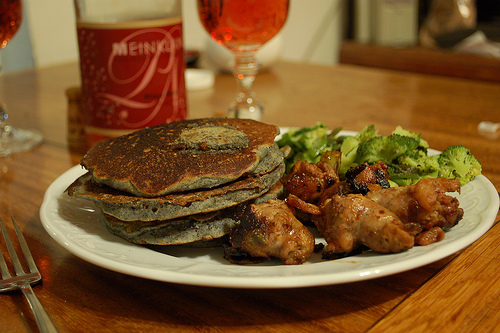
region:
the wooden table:
[8, 57, 485, 330]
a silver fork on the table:
[1, 217, 62, 331]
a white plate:
[52, 121, 487, 279]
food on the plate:
[40, 120, 499, 282]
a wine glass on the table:
[196, 8, 293, 113]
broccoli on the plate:
[294, 125, 469, 175]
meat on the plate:
[226, 175, 479, 250]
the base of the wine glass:
[228, 54, 279, 114]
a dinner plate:
[53, 113, 484, 282]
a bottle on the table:
[82, 0, 194, 119]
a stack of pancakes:
[86, 101, 314, 279]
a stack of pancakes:
[89, 123, 288, 270]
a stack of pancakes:
[69, 122, 307, 267]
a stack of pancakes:
[71, 121, 304, 305]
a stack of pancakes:
[113, 103, 295, 280]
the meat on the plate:
[239, 130, 479, 260]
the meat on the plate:
[289, 163, 464, 248]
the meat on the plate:
[241, 153, 427, 254]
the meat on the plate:
[250, 177, 410, 271]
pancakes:
[106, 134, 211, 237]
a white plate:
[178, 249, 218, 284]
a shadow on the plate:
[62, 197, 87, 222]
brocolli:
[363, 138, 419, 162]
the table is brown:
[331, 69, 419, 109]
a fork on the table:
[5, 237, 35, 288]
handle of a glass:
[232, 52, 259, 114]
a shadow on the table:
[161, 300, 253, 324]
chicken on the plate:
[297, 166, 409, 235]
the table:
[353, 69, 444, 109]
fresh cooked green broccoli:
[298, 117, 486, 181]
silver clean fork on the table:
[1, 217, 62, 327]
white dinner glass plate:
[36, 160, 208, 290]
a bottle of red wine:
[70, 10, 194, 114]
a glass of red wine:
[199, 5, 299, 112]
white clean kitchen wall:
[295, 2, 345, 62]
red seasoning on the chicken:
[343, 203, 405, 225]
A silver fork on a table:
[0, 216, 56, 331]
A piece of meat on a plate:
[237, 198, 310, 261]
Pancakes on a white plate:
[82, 115, 282, 241]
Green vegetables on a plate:
[287, 123, 480, 180]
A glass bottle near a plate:
[71, 2, 184, 142]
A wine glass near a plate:
[197, 0, 287, 121]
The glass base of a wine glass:
[1, 123, 43, 153]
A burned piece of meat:
[348, 176, 368, 191]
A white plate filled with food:
[42, 112, 498, 287]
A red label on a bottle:
[78, 14, 189, 129]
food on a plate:
[92, 132, 227, 177]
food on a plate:
[327, 190, 410, 252]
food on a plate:
[240, 197, 300, 257]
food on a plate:
[391, 157, 456, 224]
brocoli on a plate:
[431, 141, 463, 187]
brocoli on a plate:
[370, 125, 420, 161]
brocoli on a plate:
[296, 125, 322, 152]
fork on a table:
[1, 236, 61, 325]